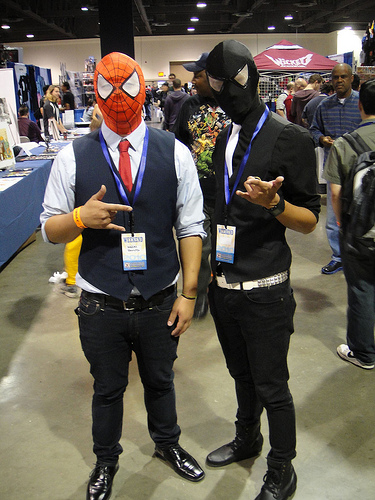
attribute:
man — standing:
[39, 50, 205, 499]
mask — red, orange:
[92, 51, 146, 133]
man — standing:
[205, 37, 321, 498]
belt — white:
[213, 271, 289, 291]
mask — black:
[204, 40, 259, 122]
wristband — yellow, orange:
[72, 206, 87, 233]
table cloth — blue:
[1, 141, 73, 268]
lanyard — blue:
[99, 126, 151, 212]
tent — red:
[251, 38, 350, 72]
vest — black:
[210, 114, 292, 282]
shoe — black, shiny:
[153, 441, 206, 482]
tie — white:
[225, 121, 241, 178]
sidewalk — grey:
[0, 197, 373, 498]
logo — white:
[264, 55, 313, 67]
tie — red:
[116, 140, 132, 192]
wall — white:
[3, 30, 365, 91]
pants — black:
[206, 280, 296, 462]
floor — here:
[0, 203, 371, 497]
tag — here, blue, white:
[118, 229, 147, 273]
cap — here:
[182, 53, 209, 73]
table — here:
[1, 140, 75, 269]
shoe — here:
[85, 460, 119, 500]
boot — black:
[205, 423, 265, 466]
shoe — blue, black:
[319, 256, 342, 274]